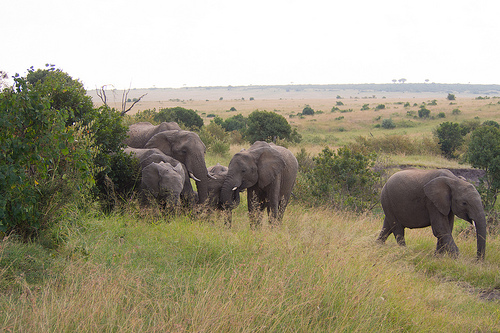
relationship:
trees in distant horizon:
[389, 76, 410, 84] [21, 72, 499, 89]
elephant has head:
[378, 165, 488, 261] [423, 171, 485, 224]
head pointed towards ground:
[423, 171, 485, 224] [5, 85, 497, 332]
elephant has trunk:
[378, 165, 488, 261] [470, 208, 485, 261]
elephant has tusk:
[378, 165, 488, 261] [468, 219, 477, 228]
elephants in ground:
[118, 115, 487, 261] [5, 85, 497, 332]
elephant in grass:
[378, 165, 488, 261] [2, 82, 496, 332]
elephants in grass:
[118, 115, 487, 261] [2, 82, 496, 332]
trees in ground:
[389, 76, 410, 84] [5, 85, 497, 332]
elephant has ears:
[378, 165, 488, 261] [420, 174, 466, 218]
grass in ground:
[2, 82, 496, 332] [5, 85, 497, 332]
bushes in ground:
[0, 62, 131, 249] [5, 85, 497, 332]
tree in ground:
[89, 80, 149, 116] [5, 85, 497, 332]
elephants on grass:
[118, 115, 487, 261] [2, 82, 496, 332]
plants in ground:
[137, 106, 302, 150] [5, 85, 497, 332]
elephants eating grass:
[118, 115, 487, 261] [2, 82, 496, 332]